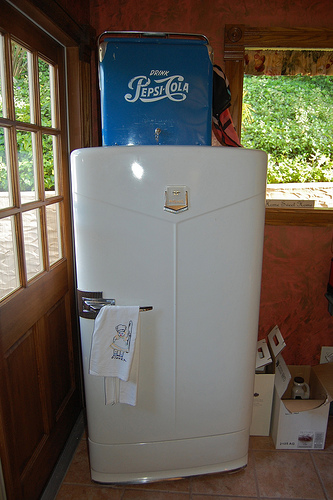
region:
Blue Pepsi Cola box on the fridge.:
[95, 29, 213, 144]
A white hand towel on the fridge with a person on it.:
[88, 305, 140, 407]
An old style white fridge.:
[69, 145, 269, 482]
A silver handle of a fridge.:
[83, 296, 153, 314]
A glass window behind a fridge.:
[241, 45, 331, 207]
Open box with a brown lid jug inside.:
[274, 355, 332, 449]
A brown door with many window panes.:
[2, 0, 85, 499]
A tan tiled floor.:
[51, 429, 332, 498]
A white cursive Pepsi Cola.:
[122, 74, 189, 101]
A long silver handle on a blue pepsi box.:
[95, 29, 209, 45]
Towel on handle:
[86, 300, 148, 407]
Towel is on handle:
[85, 304, 149, 409]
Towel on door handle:
[86, 297, 149, 409]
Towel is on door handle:
[88, 301, 147, 408]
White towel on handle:
[86, 301, 140, 409]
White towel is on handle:
[83, 298, 137, 401]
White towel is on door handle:
[85, 295, 139, 402]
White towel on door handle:
[85, 301, 140, 408]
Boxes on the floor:
[242, 327, 330, 455]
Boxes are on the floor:
[249, 323, 331, 452]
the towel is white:
[92, 303, 158, 401]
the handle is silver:
[83, 300, 156, 316]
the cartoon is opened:
[276, 365, 327, 447]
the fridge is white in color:
[77, 150, 254, 485]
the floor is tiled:
[257, 470, 314, 496]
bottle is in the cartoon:
[293, 373, 316, 400]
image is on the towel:
[114, 322, 136, 365]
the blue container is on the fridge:
[102, 40, 209, 137]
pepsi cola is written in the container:
[127, 66, 191, 105]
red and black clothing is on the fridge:
[214, 76, 241, 154]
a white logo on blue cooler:
[125, 67, 193, 103]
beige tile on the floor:
[251, 455, 323, 496]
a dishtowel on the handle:
[93, 302, 136, 409]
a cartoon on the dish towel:
[112, 322, 129, 367]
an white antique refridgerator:
[76, 150, 260, 488]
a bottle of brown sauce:
[291, 375, 315, 399]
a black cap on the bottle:
[295, 375, 303, 384]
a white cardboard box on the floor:
[270, 374, 331, 453]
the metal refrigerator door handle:
[93, 304, 154, 312]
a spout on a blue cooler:
[151, 127, 163, 136]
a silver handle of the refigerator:
[76, 291, 165, 337]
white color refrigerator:
[80, 152, 304, 481]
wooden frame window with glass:
[4, 26, 67, 309]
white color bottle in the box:
[274, 341, 331, 459]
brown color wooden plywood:
[15, 308, 68, 445]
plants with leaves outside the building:
[264, 84, 328, 171]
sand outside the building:
[25, 216, 36, 266]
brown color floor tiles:
[263, 461, 303, 498]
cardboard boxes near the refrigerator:
[259, 331, 320, 448]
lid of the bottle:
[294, 375, 304, 385]